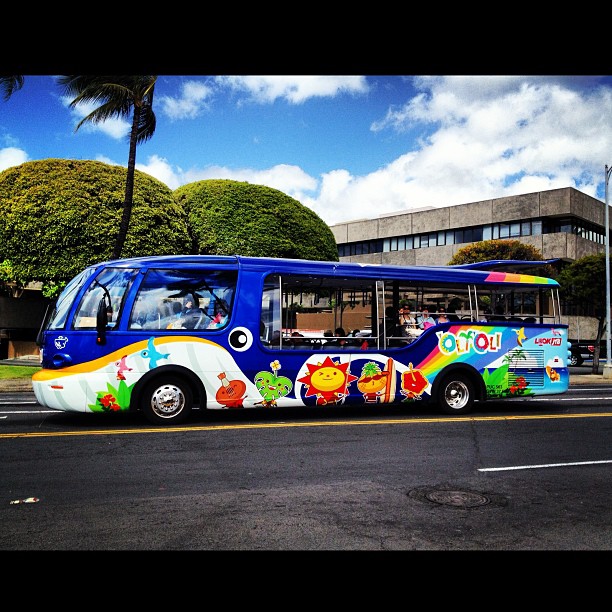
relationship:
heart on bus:
[252, 371, 293, 405] [31, 252, 573, 425]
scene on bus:
[444, 320, 565, 394] [31, 252, 573, 425]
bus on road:
[31, 252, 573, 425] [0, 384, 612, 550]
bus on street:
[31, 252, 573, 425] [37, 416, 593, 522]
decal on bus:
[302, 357, 344, 414] [50, 267, 572, 412]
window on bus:
[381, 226, 457, 248] [43, 257, 588, 407]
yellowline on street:
[12, 413, 609, 440] [1, 420, 594, 541]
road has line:
[0, 389, 612, 553] [469, 451, 593, 483]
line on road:
[469, 451, 593, 483] [0, 389, 612, 553]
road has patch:
[0, 389, 612, 553] [409, 454, 524, 553]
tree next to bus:
[2, 208, 338, 262] [50, 267, 572, 412]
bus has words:
[31, 252, 573, 425] [437, 330, 514, 354]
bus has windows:
[31, 252, 573, 425] [277, 271, 480, 329]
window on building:
[492, 224, 499, 243] [362, 215, 591, 276]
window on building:
[499, 220, 519, 240] [348, 185, 591, 269]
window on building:
[506, 215, 518, 236] [350, 201, 587, 287]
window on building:
[515, 222, 528, 236] [348, 185, 591, 269]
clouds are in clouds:
[0, 76, 609, 192] [0, 74, 611, 227]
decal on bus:
[297, 356, 358, 406] [31, 252, 573, 425]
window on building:
[528, 218, 541, 233] [306, 188, 579, 314]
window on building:
[469, 226, 482, 239] [333, 176, 591, 350]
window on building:
[440, 229, 455, 240] [339, 175, 589, 403]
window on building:
[430, 229, 442, 243] [323, 164, 584, 437]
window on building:
[412, 230, 419, 249] [327, 184, 588, 370]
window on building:
[376, 235, 388, 252] [313, 198, 571, 381]